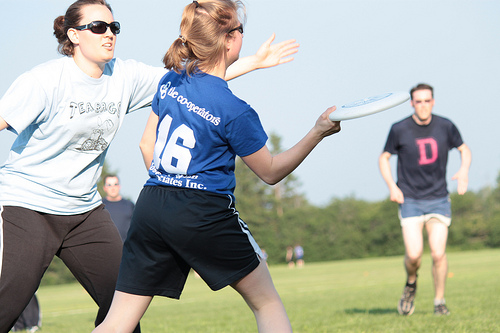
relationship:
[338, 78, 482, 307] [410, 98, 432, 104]
man wearing sunglasses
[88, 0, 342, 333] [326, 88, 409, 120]
girl holding frisbee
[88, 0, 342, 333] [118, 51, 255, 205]
girl wearing shirt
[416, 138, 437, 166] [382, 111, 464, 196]
d on shirt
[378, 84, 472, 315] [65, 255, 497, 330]
man on grass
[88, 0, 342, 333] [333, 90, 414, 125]
girl with frisbee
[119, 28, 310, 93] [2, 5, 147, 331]
arm on woman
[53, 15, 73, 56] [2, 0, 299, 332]
ponytail on woman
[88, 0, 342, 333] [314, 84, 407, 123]
girl playing frisbee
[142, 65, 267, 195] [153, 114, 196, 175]
shirt with number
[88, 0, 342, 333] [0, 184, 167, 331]
girl wears pant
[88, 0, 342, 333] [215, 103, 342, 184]
girl has arm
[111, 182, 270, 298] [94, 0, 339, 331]
shorts on girl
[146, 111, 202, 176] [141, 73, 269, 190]
number on back of shirt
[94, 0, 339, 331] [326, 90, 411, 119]
girl throwing frisbee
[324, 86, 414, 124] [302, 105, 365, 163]
frisbee in someones hand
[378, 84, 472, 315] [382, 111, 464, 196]
man in shirt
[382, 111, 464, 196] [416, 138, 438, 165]
shirt with letter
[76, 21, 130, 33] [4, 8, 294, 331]
sunglasses on female defender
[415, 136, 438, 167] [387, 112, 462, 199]
d on front of shirt